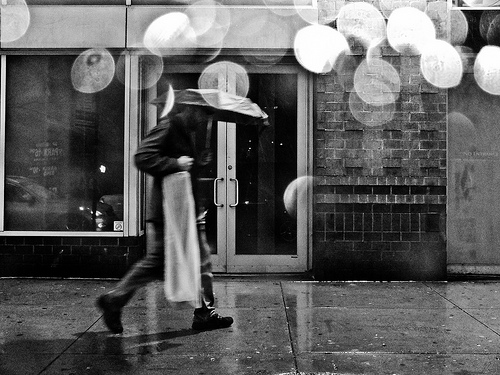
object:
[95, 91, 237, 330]
man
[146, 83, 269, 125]
umbrella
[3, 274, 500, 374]
floor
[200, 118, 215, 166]
pole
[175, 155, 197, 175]
hand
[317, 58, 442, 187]
bricks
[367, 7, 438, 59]
spots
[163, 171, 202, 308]
bag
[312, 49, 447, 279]
wall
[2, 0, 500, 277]
building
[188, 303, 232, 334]
shoes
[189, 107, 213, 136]
face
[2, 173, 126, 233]
reflection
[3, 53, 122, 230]
window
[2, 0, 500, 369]
rain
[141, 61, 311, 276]
doors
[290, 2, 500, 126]
drops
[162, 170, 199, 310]
towel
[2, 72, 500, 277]
sidewalk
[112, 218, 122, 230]
sticker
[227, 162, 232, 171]
keyhole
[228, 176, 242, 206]
handle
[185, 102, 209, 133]
hair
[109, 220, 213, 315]
pants